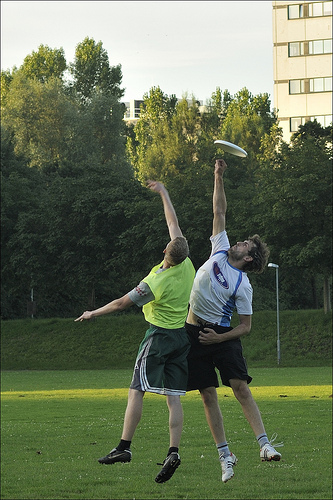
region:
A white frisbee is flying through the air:
[203, 125, 257, 179]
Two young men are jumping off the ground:
[88, 421, 309, 496]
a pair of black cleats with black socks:
[86, 427, 195, 494]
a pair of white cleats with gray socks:
[201, 430, 311, 476]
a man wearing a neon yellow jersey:
[119, 254, 205, 366]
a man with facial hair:
[215, 223, 283, 286]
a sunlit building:
[250, 15, 326, 171]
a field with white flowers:
[15, 374, 104, 495]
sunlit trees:
[9, 28, 296, 183]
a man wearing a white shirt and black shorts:
[192, 211, 272, 367]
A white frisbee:
[210, 130, 255, 163]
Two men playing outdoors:
[75, 139, 284, 482]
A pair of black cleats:
[89, 429, 180, 496]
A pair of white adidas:
[194, 417, 290, 481]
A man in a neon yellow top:
[70, 181, 198, 486]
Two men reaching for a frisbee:
[68, 136, 282, 487]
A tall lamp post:
[264, 257, 291, 365]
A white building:
[265, 0, 329, 139]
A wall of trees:
[0, 38, 323, 310]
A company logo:
[209, 260, 230, 292]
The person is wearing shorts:
[132, 329, 193, 400]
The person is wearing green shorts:
[124, 322, 199, 406]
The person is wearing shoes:
[84, 435, 216, 490]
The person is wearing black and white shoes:
[100, 420, 205, 492]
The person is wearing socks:
[114, 413, 206, 488]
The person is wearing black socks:
[113, 425, 188, 464]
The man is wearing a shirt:
[201, 228, 259, 351]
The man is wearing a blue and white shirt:
[200, 219, 258, 344]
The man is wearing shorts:
[185, 295, 250, 407]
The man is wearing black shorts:
[180, 302, 259, 402]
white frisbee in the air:
[210, 136, 252, 163]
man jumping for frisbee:
[186, 152, 282, 481]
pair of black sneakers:
[96, 444, 185, 483]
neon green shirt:
[141, 255, 193, 332]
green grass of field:
[27, 373, 102, 443]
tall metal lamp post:
[266, 260, 284, 368]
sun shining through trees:
[15, 380, 122, 402]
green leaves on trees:
[24, 104, 109, 255]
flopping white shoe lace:
[267, 428, 285, 450]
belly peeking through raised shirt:
[184, 303, 212, 327]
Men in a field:
[68, 140, 306, 484]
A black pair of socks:
[110, 438, 187, 453]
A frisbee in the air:
[189, 127, 265, 158]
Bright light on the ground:
[0, 380, 332, 402]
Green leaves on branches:
[5, 59, 329, 194]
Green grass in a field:
[5, 432, 331, 499]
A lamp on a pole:
[265, 258, 298, 367]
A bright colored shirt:
[140, 258, 198, 326]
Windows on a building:
[287, 0, 331, 136]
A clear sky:
[4, 4, 271, 80]